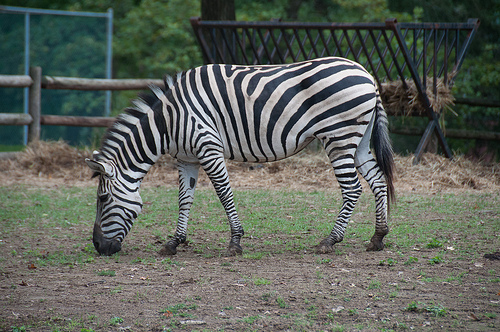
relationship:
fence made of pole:
[1, 64, 221, 162] [31, 67, 197, 98]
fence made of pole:
[1, 64, 221, 162] [32, 110, 132, 132]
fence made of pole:
[1, 64, 221, 162] [0, 69, 39, 91]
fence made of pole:
[1, 64, 221, 162] [0, 103, 41, 128]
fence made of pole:
[1, 64, 221, 162] [14, 59, 55, 158]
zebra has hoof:
[58, 53, 422, 279] [151, 235, 189, 265]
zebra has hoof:
[58, 53, 422, 279] [220, 231, 246, 266]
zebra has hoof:
[58, 53, 422, 279] [306, 230, 341, 258]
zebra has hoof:
[58, 53, 422, 279] [362, 232, 392, 258]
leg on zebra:
[195, 139, 248, 249] [58, 53, 422, 279]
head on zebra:
[86, 155, 144, 253] [58, 53, 422, 279]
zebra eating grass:
[58, 53, 422, 279] [7, 182, 477, 261]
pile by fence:
[14, 133, 96, 181] [1, 64, 221, 162]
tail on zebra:
[374, 80, 396, 207] [58, 53, 422, 279]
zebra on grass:
[58, 53, 422, 279] [7, 182, 477, 261]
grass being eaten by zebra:
[7, 182, 477, 261] [58, 53, 422, 279]